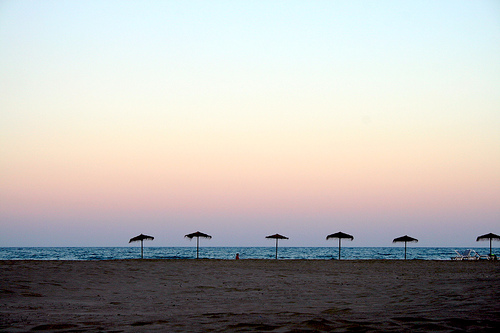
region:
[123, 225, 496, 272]
Umbrella on a sandy beach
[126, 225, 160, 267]
Umbrella on a sandy beach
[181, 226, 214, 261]
Umbrella on a sandy beach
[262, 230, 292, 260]
Umbrella on a sandy beach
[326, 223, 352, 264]
Umbrella on a sandy beach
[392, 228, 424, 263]
Umbrella on a sandy beach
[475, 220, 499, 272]
Umbrella on a sandy beach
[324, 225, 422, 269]
Umbrella on a sandy beach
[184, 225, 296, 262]
Umbrella on a sandy beach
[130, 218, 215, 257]
Umbrella on a sandy beach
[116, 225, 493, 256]
parasols in front the ocean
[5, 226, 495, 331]
parasols on the beack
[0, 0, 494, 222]
the sky is color blue and orange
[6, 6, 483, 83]
sky color blue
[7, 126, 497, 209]
sky color orange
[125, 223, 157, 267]
a parasol in the beach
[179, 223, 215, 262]
a parasol in the beach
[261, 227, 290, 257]
a parasol in the beach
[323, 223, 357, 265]
a parasol in the beach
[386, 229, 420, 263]
a parasol in the beach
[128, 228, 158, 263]
Umbrella in the sand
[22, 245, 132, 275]
water washing up on the beach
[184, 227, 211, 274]
umbrella on the beach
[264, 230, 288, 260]
umbrella on the beach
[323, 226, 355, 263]
umbrella on the beach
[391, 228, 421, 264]
umbrella on the beach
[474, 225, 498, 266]
umbrella on the beach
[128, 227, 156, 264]
umbrella on the beach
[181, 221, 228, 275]
umbrella on the beach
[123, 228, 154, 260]
Umbrella on the beach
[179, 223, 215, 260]
Straw umbrella on the beach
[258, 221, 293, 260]
Straw umbrella on the beach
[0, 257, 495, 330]
Brown sand on beach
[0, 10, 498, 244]
Sky covering the background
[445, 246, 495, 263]
White chairs on sand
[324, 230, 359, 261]
Umbrella on the beach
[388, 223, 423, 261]
Umbrella on the beach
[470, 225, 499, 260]
Umbrella on the beach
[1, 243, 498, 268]
Water behind the umbrellas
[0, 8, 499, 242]
evening with colorful sunset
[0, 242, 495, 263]
calm water on the beach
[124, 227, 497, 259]
umbrellas line the beach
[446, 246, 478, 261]
a picnic table in distance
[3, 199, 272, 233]
purple color from sunset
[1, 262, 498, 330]
sandy beach in evening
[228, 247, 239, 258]
someone sitting on beach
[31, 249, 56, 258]
waves of water in distance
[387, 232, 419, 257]
one of six umbrellas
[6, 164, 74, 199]
pink color of sunset